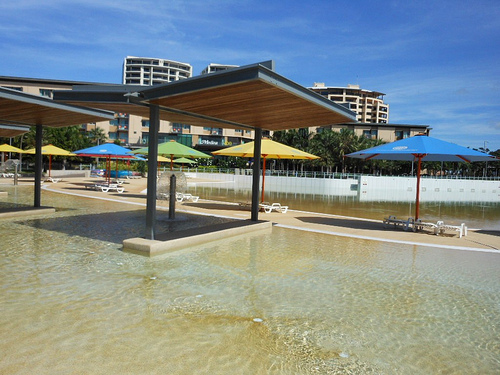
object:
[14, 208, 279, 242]
shadow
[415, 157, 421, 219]
pole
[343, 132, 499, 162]
umbrella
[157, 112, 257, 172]
hotel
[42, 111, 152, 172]
hotel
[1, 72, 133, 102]
hotel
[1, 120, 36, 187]
hotel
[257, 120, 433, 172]
hotel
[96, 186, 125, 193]
chair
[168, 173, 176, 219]
pole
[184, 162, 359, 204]
reflection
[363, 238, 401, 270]
sea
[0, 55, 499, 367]
resorts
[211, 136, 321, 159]
umbrella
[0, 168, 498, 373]
beach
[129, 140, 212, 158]
umbrella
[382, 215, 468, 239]
chair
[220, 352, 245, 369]
ripple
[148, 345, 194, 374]
ripple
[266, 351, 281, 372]
ripple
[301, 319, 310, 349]
ripple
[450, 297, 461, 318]
ripple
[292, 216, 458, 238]
shadow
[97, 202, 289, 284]
water